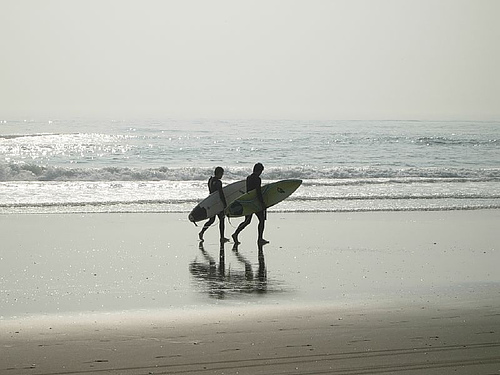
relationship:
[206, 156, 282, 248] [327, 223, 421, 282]
surfers on beach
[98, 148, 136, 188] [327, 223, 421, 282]
wave on beach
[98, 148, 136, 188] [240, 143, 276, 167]
wave on water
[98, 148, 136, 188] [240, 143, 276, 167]
wave in water